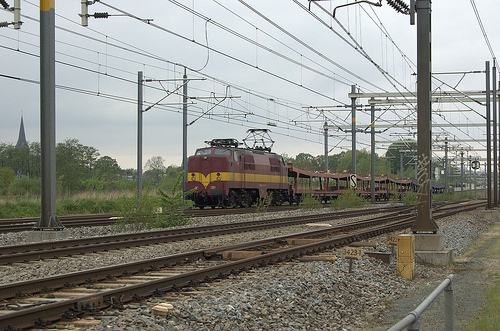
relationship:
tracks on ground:
[2, 194, 499, 329] [378, 227, 498, 329]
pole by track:
[406, 0, 438, 234] [90, 203, 406, 300]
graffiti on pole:
[426, 182, 436, 226] [406, 0, 441, 239]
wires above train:
[198, 14, 417, 96] [178, 140, 303, 225]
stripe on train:
[185, 168, 288, 184] [183, 136, 419, 207]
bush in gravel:
[112, 190, 154, 232] [6, 205, 336, 246]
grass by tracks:
[3, 192, 187, 217] [2, 203, 303, 234]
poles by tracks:
[26, 0, 467, 195] [2, 194, 499, 329]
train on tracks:
[176, 134, 454, 210] [2, 194, 499, 329]